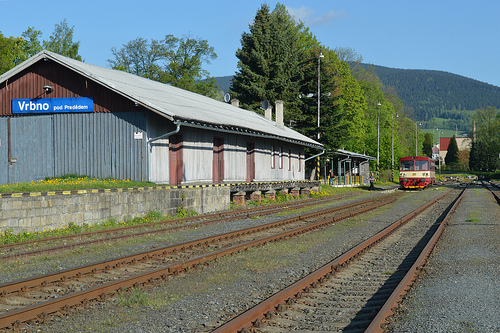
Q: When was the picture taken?
A: Daytime.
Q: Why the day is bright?
A: It's sunny.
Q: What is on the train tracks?
A: A train.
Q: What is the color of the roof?
A: Gray.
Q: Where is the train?
A: On the train tracks.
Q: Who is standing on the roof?
A: No one.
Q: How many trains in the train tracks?
A: One.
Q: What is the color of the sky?
A: Blue.